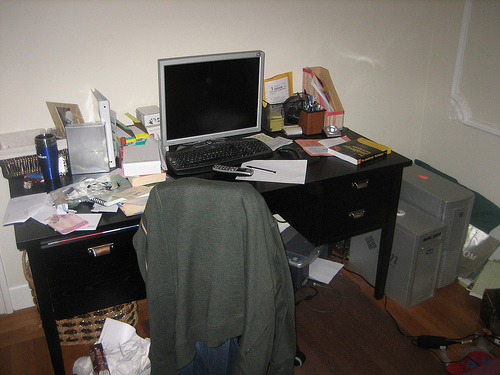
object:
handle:
[351, 179, 369, 190]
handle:
[348, 208, 366, 220]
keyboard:
[168, 136, 271, 178]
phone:
[52, 172, 115, 205]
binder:
[90, 87, 116, 170]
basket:
[37, 302, 136, 347]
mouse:
[275, 145, 303, 160]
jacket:
[123, 180, 295, 375]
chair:
[126, 179, 306, 375]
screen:
[164, 57, 258, 142]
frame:
[46, 101, 84, 136]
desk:
[12, 113, 403, 296]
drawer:
[317, 167, 404, 220]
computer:
[397, 162, 474, 290]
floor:
[290, 261, 498, 372]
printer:
[279, 236, 347, 293]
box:
[65, 121, 106, 177]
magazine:
[327, 136, 394, 166]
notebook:
[93, 190, 123, 208]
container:
[33, 130, 60, 181]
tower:
[345, 201, 452, 312]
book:
[119, 141, 161, 178]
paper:
[236, 159, 309, 186]